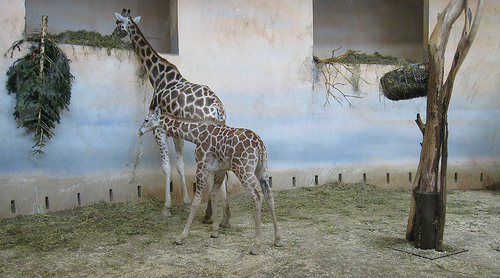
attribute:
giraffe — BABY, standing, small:
[137, 100, 287, 255]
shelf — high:
[22, 22, 184, 62]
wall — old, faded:
[5, 11, 497, 200]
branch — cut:
[13, 20, 69, 153]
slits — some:
[8, 149, 498, 213]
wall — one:
[2, 7, 490, 230]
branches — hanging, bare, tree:
[313, 50, 373, 110]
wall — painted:
[255, 94, 481, 178]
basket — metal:
[406, 57, 436, 111]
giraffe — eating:
[101, 3, 230, 213]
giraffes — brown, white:
[106, 4, 291, 258]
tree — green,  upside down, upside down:
[4, 12, 78, 157]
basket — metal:
[377, 61, 431, 102]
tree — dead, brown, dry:
[402, 4, 482, 247]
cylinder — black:
[399, 184, 449, 249]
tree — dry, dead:
[397, 1, 493, 259]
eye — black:
[146, 119, 153, 124]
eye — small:
[142, 117, 150, 123]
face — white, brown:
[137, 110, 156, 133]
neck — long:
[126, 17, 178, 85]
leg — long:
[153, 128, 172, 218]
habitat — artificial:
[2, 1, 484, 274]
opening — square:
[24, 1, 177, 55]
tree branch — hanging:
[4, 14, 74, 161]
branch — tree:
[4, 9, 77, 161]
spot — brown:
[242, 131, 253, 152]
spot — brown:
[231, 144, 248, 160]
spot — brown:
[226, 150, 241, 170]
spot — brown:
[242, 161, 252, 179]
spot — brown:
[168, 117, 179, 131]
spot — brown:
[188, 118, 196, 133]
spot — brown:
[194, 90, 210, 110]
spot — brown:
[176, 85, 186, 105]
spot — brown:
[147, 62, 159, 81]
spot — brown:
[136, 35, 154, 57]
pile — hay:
[283, 170, 409, 221]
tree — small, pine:
[6, 13, 85, 157]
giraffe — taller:
[98, 6, 249, 256]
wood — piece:
[405, 188, 445, 256]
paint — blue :
[220, 75, 370, 220]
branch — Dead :
[287, 25, 419, 111]